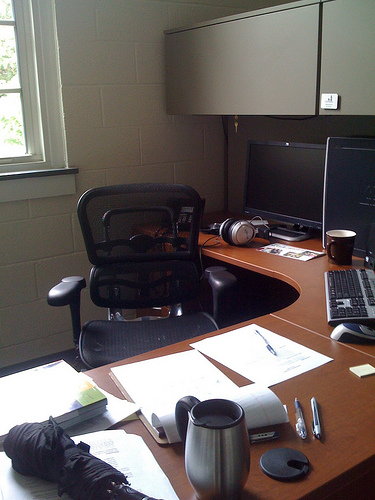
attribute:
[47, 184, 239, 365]
office chair — black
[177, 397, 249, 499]
mug — metal, silver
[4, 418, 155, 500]
umbrella — black, folded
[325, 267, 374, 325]
keyboard — gray, black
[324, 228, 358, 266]
mug — brown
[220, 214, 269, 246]
headphones — folded, large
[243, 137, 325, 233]
computer monitor — powered off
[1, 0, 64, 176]
window — white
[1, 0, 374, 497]
computer office — small